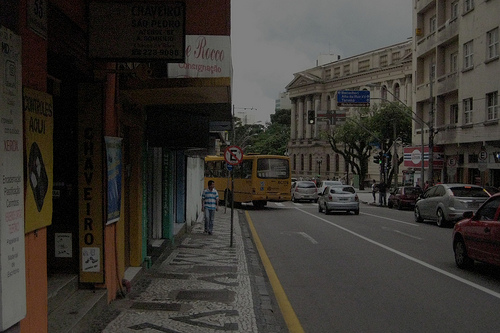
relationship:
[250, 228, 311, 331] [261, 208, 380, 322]
line on road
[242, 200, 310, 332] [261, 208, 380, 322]
line on road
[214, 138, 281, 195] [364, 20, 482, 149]
sign on building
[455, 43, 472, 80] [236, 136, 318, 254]
window on bus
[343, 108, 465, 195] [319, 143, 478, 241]
trees on sidewalk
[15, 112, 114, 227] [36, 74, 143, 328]
sign on doorway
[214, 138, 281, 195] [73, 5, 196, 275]
sign front building